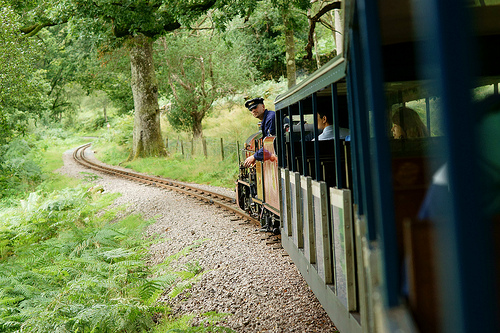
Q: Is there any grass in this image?
A: Yes, there is grass.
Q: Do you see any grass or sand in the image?
A: Yes, there is grass.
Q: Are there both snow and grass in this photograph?
A: No, there is grass but no snow.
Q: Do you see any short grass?
A: Yes, there is short grass.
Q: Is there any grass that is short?
A: Yes, there is grass that is short.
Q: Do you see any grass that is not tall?
A: Yes, there is short grass.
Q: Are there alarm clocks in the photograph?
A: No, there are no alarm clocks.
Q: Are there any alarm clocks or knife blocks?
A: No, there are no alarm clocks or knife blocks.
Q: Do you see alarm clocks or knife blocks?
A: No, there are no alarm clocks or knife blocks.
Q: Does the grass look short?
A: Yes, the grass is short.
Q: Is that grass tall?
A: No, the grass is short.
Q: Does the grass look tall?
A: No, the grass is short.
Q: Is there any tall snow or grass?
A: No, there is grass but it is short.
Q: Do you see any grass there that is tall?
A: No, there is grass but it is short.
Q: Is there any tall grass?
A: No, there is grass but it is short.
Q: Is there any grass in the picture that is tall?
A: No, there is grass but it is short.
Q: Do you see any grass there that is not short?
A: No, there is grass but it is short.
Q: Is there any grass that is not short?
A: No, there is grass but it is short.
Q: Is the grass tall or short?
A: The grass is short.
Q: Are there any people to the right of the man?
A: Yes, there is a person to the right of the man.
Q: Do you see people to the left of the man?
A: No, the person is to the right of the man.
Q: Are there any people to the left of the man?
A: No, the person is to the right of the man.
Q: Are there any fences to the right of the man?
A: No, there is a person to the right of the man.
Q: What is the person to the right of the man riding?
A: The person is riding the train.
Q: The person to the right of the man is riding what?
A: The person is riding the train.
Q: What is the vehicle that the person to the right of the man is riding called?
A: The vehicle is a train.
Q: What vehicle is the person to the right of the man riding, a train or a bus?
A: The person is riding a train.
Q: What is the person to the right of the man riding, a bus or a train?
A: The person is riding a train.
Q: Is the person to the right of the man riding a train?
A: Yes, the person is riding a train.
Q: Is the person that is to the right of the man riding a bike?
A: No, the person is riding a train.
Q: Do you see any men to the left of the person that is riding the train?
A: Yes, there is a man to the left of the person.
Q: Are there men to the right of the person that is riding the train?
A: No, the man is to the left of the person.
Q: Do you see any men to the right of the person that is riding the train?
A: No, the man is to the left of the person.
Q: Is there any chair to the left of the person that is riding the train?
A: No, there is a man to the left of the person.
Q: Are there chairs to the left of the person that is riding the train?
A: No, there is a man to the left of the person.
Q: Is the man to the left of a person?
A: Yes, the man is to the left of a person.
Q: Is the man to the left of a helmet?
A: No, the man is to the left of a person.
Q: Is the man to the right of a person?
A: No, the man is to the left of a person.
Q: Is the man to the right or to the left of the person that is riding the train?
A: The man is to the left of the person.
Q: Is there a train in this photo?
A: Yes, there is a train.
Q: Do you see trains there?
A: Yes, there is a train.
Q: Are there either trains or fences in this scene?
A: Yes, there is a train.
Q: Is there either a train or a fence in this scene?
A: Yes, there is a train.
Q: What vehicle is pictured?
A: The vehicle is a train.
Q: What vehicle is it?
A: The vehicle is a train.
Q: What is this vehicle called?
A: That is a train.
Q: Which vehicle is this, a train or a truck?
A: That is a train.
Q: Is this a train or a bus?
A: This is a train.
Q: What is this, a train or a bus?
A: This is a train.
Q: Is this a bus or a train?
A: This is a train.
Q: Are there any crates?
A: No, there are no crates.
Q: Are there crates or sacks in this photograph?
A: No, there are no crates or sacks.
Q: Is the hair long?
A: Yes, the hair is long.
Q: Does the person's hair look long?
A: Yes, the hair is long.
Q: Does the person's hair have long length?
A: Yes, the hair is long.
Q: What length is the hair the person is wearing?
A: The hair is long.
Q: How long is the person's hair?
A: The hair is long.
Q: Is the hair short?
A: No, the hair is long.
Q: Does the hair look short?
A: No, the hair is long.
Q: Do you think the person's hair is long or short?
A: The hair is long.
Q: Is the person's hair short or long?
A: The hair is long.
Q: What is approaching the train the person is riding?
A: The tree is approaching the train.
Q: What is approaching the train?
A: The tree is approaching the train.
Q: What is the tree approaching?
A: The tree is approaching the train.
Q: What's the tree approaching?
A: The tree is approaching the train.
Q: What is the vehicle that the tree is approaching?
A: The vehicle is a train.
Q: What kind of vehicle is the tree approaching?
A: The tree is approaching the train.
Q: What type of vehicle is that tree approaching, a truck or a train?
A: The tree is approaching a train.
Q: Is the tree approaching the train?
A: Yes, the tree is approaching the train.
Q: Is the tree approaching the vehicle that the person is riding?
A: Yes, the tree is approaching the train.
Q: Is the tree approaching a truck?
A: No, the tree is approaching the train.